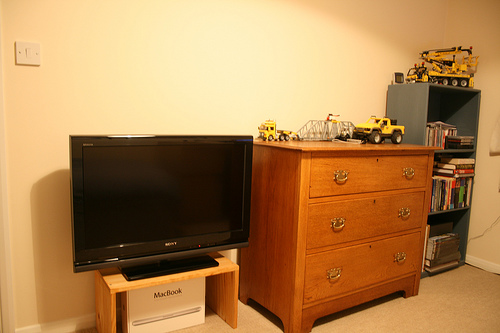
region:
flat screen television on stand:
[41, 108, 278, 322]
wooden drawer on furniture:
[385, 235, 437, 293]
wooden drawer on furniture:
[380, 183, 425, 241]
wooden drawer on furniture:
[311, 242, 366, 302]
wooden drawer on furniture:
[302, 189, 374, 247]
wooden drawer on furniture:
[378, 158, 432, 190]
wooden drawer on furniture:
[308, 151, 368, 208]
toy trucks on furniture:
[351, 102, 412, 157]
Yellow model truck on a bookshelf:
[406, 43, 480, 90]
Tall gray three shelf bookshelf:
[385, 78, 482, 278]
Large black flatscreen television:
[63, 128, 255, 268]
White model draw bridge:
[291, 117, 356, 142]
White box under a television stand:
[121, 276, 208, 331]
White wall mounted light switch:
[12, 38, 45, 68]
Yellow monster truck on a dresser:
[352, 113, 404, 144]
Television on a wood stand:
[64, 133, 254, 332]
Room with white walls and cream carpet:
[0, 0, 498, 331]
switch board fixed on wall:
[13, 42, 39, 67]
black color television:
[74, 137, 248, 251]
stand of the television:
[126, 265, 217, 275]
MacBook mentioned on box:
[133, 287, 202, 330]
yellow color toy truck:
[358, 119, 405, 144]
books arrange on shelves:
[431, 106, 476, 148]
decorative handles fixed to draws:
[330, 217, 346, 230]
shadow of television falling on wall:
[30, 183, 70, 313]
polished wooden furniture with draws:
[266, 144, 419, 296]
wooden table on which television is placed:
[98, 269, 120, 330]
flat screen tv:
[53, 123, 261, 288]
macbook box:
[117, 270, 223, 330]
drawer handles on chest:
[325, 160, 357, 186]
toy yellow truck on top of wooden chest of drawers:
[353, 115, 408, 148]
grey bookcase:
[382, 75, 479, 281]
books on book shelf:
[437, 154, 476, 211]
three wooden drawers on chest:
[305, 156, 434, 312]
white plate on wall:
[6, 35, 46, 74]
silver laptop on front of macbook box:
[128, 303, 205, 330]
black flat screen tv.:
[71, 133, 251, 265]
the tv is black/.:
[67, 132, 257, 267]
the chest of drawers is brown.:
[250, 132, 430, 325]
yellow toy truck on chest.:
[352, 111, 402, 141]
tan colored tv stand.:
[87, 252, 237, 329]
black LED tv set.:
[67, 130, 254, 261]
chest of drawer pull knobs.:
[330, 165, 417, 181]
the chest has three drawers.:
[303, 151, 423, 293]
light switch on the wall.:
[13, 37, 41, 64]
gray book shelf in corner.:
[381, 78, 479, 274]